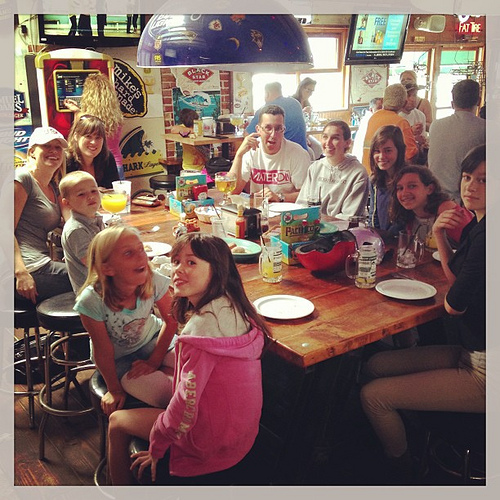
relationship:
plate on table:
[377, 282, 438, 305] [357, 318, 395, 330]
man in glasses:
[243, 119, 316, 206] [265, 122, 286, 144]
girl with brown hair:
[154, 236, 285, 441] [175, 238, 270, 311]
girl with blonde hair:
[84, 234, 181, 402] [84, 220, 150, 258]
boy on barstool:
[53, 177, 126, 293] [47, 297, 96, 355]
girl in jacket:
[154, 236, 285, 441] [181, 346, 279, 407]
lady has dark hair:
[363, 130, 406, 222] [370, 123, 423, 152]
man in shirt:
[243, 119, 316, 206] [243, 136, 311, 191]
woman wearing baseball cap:
[17, 110, 65, 313] [16, 121, 98, 146]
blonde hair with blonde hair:
[74, 226, 157, 313] [83, 73, 113, 112]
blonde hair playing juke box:
[74, 226, 157, 313] [38, 57, 75, 103]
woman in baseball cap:
[17, 110, 65, 313] [16, 121, 98, 146]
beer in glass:
[217, 183, 224, 184] [216, 167, 237, 212]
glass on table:
[216, 167, 237, 212] [357, 318, 395, 330]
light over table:
[121, 9, 330, 84] [357, 318, 395, 330]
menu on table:
[281, 216, 332, 237] [357, 318, 395, 330]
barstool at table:
[47, 297, 96, 355] [357, 318, 395, 330]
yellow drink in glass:
[102, 189, 126, 207] [99, 182, 149, 231]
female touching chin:
[423, 153, 499, 439] [463, 200, 484, 221]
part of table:
[295, 346, 334, 380] [357, 318, 395, 330]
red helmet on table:
[304, 233, 349, 260] [357, 318, 395, 330]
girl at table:
[106, 229, 275, 484] [357, 318, 395, 330]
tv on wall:
[346, 18, 420, 67] [339, 19, 353, 28]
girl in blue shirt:
[154, 236, 285, 441] [69, 295, 185, 352]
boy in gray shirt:
[53, 177, 126, 293] [52, 216, 92, 280]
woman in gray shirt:
[17, 110, 65, 313] [19, 173, 55, 246]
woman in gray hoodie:
[302, 110, 360, 219] [316, 162, 376, 227]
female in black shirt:
[423, 153, 499, 439] [456, 234, 485, 336]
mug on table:
[347, 244, 395, 293] [357, 318, 395, 330]